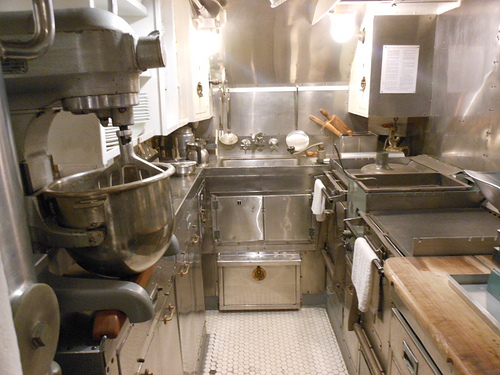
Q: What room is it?
A: It is a kitchen.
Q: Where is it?
A: This is at the kitchen.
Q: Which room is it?
A: It is a kitchen.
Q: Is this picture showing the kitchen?
A: Yes, it is showing the kitchen.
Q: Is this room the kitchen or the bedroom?
A: It is the kitchen.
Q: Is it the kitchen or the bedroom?
A: It is the kitchen.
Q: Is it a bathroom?
A: No, it is a kitchen.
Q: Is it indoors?
A: Yes, it is indoors.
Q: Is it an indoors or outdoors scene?
A: It is indoors.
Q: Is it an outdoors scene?
A: No, it is indoors.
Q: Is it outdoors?
A: No, it is indoors.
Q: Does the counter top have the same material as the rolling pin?
A: Yes, both the counter top and the rolling pin are made of wood.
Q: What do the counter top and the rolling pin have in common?
A: The material, both the counter top and the rolling pin are wooden.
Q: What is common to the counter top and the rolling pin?
A: The material, both the counter top and the rolling pin are wooden.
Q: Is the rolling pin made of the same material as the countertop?
A: Yes, both the rolling pin and the countertop are made of wood.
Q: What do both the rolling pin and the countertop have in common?
A: The material, both the rolling pin and the countertop are wooden.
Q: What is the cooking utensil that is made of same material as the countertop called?
A: The cooking utensil is a rolling pin.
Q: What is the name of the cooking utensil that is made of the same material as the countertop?
A: The cooking utensil is a rolling pin.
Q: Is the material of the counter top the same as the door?
A: No, the counter top is made of wood and the door is made of metal.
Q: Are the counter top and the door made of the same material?
A: No, the counter top is made of wood and the door is made of metal.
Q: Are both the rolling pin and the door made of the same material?
A: No, the rolling pin is made of wood and the door is made of metal.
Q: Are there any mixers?
A: Yes, there is a mixer.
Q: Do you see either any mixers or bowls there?
A: Yes, there is a mixer.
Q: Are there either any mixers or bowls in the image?
A: Yes, there is a mixer.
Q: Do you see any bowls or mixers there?
A: Yes, there is a mixer.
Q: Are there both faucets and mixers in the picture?
A: Yes, there are both a mixer and a faucet.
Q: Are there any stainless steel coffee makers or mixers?
A: Yes, there is a stainless steel mixer.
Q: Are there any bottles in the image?
A: No, there are no bottles.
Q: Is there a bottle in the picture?
A: No, there are no bottles.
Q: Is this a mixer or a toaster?
A: This is a mixer.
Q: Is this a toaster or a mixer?
A: This is a mixer.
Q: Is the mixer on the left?
A: Yes, the mixer is on the left of the image.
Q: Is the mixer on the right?
A: No, the mixer is on the left of the image.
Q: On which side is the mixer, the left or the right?
A: The mixer is on the left of the image.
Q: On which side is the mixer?
A: The mixer is on the left of the image.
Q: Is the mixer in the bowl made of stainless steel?
A: Yes, the mixer is made of stainless steel.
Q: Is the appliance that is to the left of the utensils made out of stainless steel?
A: Yes, the mixer is made of stainless steel.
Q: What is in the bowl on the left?
A: The mixer is in the bowl.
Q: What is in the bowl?
A: The mixer is in the bowl.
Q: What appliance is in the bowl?
A: The appliance is a mixer.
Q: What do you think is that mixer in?
A: The mixer is in the bowl.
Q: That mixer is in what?
A: The mixer is in the bowl.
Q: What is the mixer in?
A: The mixer is in the bowl.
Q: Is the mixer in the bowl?
A: Yes, the mixer is in the bowl.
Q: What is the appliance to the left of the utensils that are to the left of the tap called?
A: The appliance is a mixer.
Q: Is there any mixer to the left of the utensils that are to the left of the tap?
A: Yes, there is a mixer to the left of the utensils.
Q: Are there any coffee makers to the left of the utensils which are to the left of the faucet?
A: No, there is a mixer to the left of the utensils.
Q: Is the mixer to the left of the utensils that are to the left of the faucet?
A: Yes, the mixer is to the left of the utensils.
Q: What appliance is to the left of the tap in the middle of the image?
A: The appliance is a mixer.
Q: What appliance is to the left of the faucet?
A: The appliance is a mixer.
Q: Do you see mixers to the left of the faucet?
A: Yes, there is a mixer to the left of the faucet.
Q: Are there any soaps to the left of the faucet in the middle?
A: No, there is a mixer to the left of the faucet.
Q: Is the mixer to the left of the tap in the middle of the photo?
A: Yes, the mixer is to the left of the faucet.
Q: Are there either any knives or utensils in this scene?
A: Yes, there are utensils.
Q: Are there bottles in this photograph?
A: No, there are no bottles.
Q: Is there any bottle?
A: No, there are no bottles.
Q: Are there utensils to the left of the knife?
A: Yes, there are utensils to the left of the knife.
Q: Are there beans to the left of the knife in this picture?
A: No, there are utensils to the left of the knife.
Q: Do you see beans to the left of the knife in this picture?
A: No, there are utensils to the left of the knife.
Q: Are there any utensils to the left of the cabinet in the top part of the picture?
A: Yes, there are utensils to the left of the cabinet.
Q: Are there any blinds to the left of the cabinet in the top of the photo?
A: No, there are utensils to the left of the cabinet.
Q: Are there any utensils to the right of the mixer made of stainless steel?
A: Yes, there are utensils to the right of the mixer.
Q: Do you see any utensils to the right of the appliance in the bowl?
A: Yes, there are utensils to the right of the mixer.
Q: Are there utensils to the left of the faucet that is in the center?
A: Yes, there are utensils to the left of the tap.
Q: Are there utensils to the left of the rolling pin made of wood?
A: Yes, there are utensils to the left of the rolling pin.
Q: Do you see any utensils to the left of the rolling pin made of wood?
A: Yes, there are utensils to the left of the rolling pin.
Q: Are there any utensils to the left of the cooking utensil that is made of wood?
A: Yes, there are utensils to the left of the rolling pin.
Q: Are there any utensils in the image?
A: Yes, there are utensils.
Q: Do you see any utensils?
A: Yes, there are utensils.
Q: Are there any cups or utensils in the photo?
A: Yes, there are utensils.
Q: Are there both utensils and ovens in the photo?
A: Yes, there are both utensils and an oven.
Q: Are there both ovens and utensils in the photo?
A: Yes, there are both utensils and an oven.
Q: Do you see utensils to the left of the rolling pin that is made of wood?
A: Yes, there are utensils to the left of the rolling pin.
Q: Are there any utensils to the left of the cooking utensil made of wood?
A: Yes, there are utensils to the left of the rolling pin.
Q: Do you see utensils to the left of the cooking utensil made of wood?
A: Yes, there are utensils to the left of the rolling pin.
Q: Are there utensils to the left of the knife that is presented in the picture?
A: Yes, there are utensils to the left of the knife.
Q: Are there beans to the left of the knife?
A: No, there are utensils to the left of the knife.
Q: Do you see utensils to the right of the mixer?
A: Yes, there are utensils to the right of the mixer.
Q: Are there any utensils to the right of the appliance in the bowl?
A: Yes, there are utensils to the right of the mixer.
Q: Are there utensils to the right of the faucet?
A: Yes, there are utensils to the right of the faucet.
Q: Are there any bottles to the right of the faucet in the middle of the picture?
A: No, there are utensils to the right of the faucet.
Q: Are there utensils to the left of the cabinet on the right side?
A: Yes, there are utensils to the left of the cabinet.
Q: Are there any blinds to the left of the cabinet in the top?
A: No, there are utensils to the left of the cabinet.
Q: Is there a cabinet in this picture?
A: Yes, there is a cabinet.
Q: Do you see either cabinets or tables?
A: Yes, there is a cabinet.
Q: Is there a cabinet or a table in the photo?
A: Yes, there is a cabinet.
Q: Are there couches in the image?
A: No, there are no couches.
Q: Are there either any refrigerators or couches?
A: No, there are no couches or refrigerators.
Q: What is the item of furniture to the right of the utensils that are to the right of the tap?
A: The piece of furniture is a cabinet.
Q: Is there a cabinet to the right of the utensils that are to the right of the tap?
A: Yes, there is a cabinet to the right of the utensils.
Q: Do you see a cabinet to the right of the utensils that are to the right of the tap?
A: Yes, there is a cabinet to the right of the utensils.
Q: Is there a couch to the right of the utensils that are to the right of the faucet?
A: No, there is a cabinet to the right of the utensils.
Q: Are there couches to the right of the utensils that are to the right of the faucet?
A: No, there is a cabinet to the right of the utensils.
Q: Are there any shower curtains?
A: No, there are no shower curtains.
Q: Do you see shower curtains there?
A: No, there are no shower curtains.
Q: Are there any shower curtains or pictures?
A: No, there are no shower curtains or pictures.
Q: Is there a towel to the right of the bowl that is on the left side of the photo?
A: Yes, there are towels to the right of the bowl.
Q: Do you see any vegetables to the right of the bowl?
A: No, there are towels to the right of the bowl.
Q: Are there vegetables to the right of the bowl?
A: No, there are towels to the right of the bowl.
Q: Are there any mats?
A: No, there are no mats.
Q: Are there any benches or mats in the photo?
A: No, there are no mats or benches.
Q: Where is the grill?
A: The grill is in the kitchen.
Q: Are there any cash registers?
A: No, there are no cash registers.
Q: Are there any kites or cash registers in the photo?
A: No, there are no cash registers or kites.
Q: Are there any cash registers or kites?
A: No, there are no cash registers or kites.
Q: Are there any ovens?
A: Yes, there is an oven.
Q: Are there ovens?
A: Yes, there is an oven.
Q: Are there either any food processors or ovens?
A: Yes, there is an oven.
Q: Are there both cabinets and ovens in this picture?
A: Yes, there are both an oven and a cabinet.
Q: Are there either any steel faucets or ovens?
A: Yes, there is a steel oven.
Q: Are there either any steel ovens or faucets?
A: Yes, there is a steel oven.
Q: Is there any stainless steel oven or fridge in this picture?
A: Yes, there is a stainless steel oven.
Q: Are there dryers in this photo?
A: No, there are no dryers.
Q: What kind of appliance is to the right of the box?
A: The appliance is an oven.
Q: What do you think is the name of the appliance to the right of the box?
A: The appliance is an oven.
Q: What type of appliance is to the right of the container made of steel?
A: The appliance is an oven.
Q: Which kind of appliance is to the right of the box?
A: The appliance is an oven.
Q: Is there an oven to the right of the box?
A: Yes, there is an oven to the right of the box.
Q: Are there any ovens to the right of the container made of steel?
A: Yes, there is an oven to the right of the box.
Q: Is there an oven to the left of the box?
A: No, the oven is to the right of the box.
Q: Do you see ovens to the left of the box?
A: No, the oven is to the right of the box.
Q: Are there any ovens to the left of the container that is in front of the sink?
A: No, the oven is to the right of the box.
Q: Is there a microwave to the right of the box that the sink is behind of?
A: No, there is an oven to the right of the box.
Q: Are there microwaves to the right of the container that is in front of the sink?
A: No, there is an oven to the right of the box.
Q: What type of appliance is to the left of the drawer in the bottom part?
A: The appliance is an oven.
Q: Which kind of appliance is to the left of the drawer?
A: The appliance is an oven.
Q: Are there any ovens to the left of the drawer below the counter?
A: Yes, there is an oven to the left of the drawer.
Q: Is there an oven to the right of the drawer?
A: No, the oven is to the left of the drawer.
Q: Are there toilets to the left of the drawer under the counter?
A: No, there is an oven to the left of the drawer.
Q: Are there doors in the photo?
A: Yes, there is a door.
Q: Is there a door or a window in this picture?
A: Yes, there is a door.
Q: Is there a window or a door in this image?
A: Yes, there is a door.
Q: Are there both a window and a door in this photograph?
A: No, there is a door but no windows.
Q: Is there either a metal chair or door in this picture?
A: Yes, there is a metal door.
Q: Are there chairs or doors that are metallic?
A: Yes, the door is metallic.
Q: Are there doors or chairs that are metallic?
A: Yes, the door is metallic.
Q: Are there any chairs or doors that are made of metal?
A: Yes, the door is made of metal.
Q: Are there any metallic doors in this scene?
A: Yes, there is a metal door.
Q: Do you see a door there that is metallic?
A: Yes, there is a door that is metallic.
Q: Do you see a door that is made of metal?
A: Yes, there is a door that is made of metal.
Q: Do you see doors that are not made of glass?
A: Yes, there is a door that is made of metal.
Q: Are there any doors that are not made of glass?
A: Yes, there is a door that is made of metal.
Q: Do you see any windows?
A: No, there are no windows.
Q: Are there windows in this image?
A: No, there are no windows.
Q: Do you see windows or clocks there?
A: No, there are no windows or clocks.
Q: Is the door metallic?
A: Yes, the door is metallic.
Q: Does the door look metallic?
A: Yes, the door is metallic.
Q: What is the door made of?
A: The door is made of metal.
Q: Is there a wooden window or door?
A: No, there is a door but it is metallic.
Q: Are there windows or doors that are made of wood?
A: No, there is a door but it is made of metal.